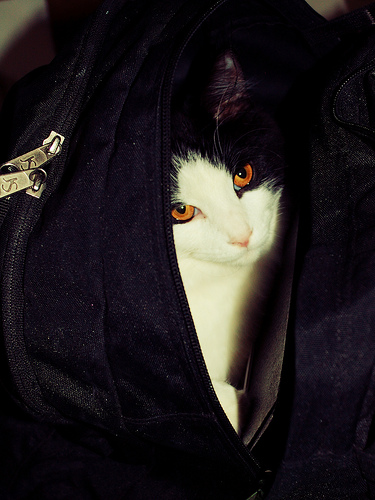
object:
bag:
[0, 0, 375, 499]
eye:
[168, 201, 197, 223]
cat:
[165, 48, 288, 433]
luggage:
[1, 0, 373, 497]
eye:
[231, 161, 259, 191]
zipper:
[0, 67, 95, 454]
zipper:
[0, 130, 66, 205]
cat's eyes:
[169, 157, 252, 223]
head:
[169, 49, 285, 272]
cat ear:
[208, 44, 253, 119]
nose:
[223, 219, 255, 249]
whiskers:
[178, 185, 282, 269]